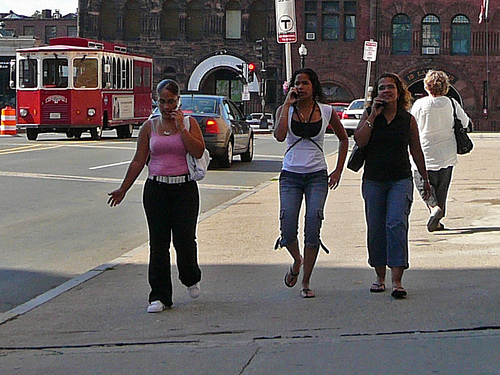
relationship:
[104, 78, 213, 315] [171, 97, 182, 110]
woman talking on her cell phone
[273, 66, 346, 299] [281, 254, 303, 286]
woman wearing sandals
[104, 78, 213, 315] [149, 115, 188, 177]
woman wearing pink shirt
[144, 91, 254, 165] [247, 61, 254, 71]
car stopped at streetlight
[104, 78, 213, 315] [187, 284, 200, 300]
woman wearing white shoes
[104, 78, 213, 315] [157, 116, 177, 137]
woman wearing necklace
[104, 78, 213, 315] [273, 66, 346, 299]
woman walking next to woman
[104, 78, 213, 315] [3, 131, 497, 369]
woman walking on sidewalk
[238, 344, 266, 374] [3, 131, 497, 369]
crack on sidewalk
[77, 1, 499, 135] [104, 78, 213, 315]
building behind woman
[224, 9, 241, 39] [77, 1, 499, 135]
window on front of building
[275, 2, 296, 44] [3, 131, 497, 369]
sign on sidewalk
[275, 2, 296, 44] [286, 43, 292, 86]
sign on pole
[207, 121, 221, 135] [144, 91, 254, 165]
light on car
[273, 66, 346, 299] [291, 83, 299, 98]
woman talking on cell phone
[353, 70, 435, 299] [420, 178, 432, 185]
woman wearing bracelet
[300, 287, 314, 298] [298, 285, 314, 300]
sandal on foot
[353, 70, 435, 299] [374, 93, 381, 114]
woman holding cell phone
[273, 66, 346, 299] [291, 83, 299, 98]
woman holding cell phone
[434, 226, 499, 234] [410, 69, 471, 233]
shadow of woman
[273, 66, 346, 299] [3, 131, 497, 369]
woman walking on sidewalk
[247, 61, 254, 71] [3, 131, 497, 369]
streetlight behind sidewalk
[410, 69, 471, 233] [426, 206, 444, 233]
woman wearing shoe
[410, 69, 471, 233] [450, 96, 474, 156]
woman holding purse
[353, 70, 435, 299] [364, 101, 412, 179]
woman wearing black shirt